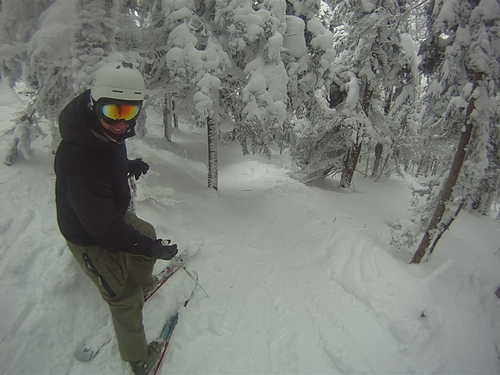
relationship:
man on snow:
[63, 59, 163, 175] [187, 281, 237, 366]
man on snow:
[51, 59, 177, 375] [111, 162, 229, 312]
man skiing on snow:
[51, 59, 177, 375] [303, 199, 418, 309]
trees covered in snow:
[2, 2, 498, 277] [140, 139, 253, 362]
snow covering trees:
[151, 16, 310, 101] [2, 2, 498, 277]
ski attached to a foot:
[74, 243, 198, 375] [130, 338, 165, 373]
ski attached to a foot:
[74, 243, 198, 375] [143, 274, 159, 298]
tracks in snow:
[220, 201, 420, 373] [223, 203, 381, 374]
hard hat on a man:
[88, 66, 145, 139] [51, 59, 177, 375]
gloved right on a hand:
[152, 238, 180, 261] [154, 236, 174, 258]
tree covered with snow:
[193, 10, 250, 207] [242, 57, 284, 101]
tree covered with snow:
[409, 3, 497, 268] [122, 102, 498, 372]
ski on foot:
[74, 243, 198, 375] [137, 336, 154, 373]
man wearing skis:
[51, 59, 177, 375] [75, 237, 198, 371]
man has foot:
[51, 59, 177, 375] [139, 275, 158, 302]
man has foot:
[51, 59, 177, 375] [135, 335, 164, 374]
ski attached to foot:
[74, 243, 198, 375] [139, 275, 158, 302]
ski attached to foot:
[143, 268, 198, 374] [135, 335, 164, 374]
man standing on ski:
[51, 59, 177, 375] [74, 243, 198, 375]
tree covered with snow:
[281, 0, 421, 193] [0, 0, 497, 371]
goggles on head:
[94, 102, 146, 122] [85, 56, 148, 143]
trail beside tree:
[177, 125, 437, 246] [163, 0, 274, 190]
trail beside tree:
[177, 125, 437, 246] [290, 2, 430, 185]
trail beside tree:
[177, 125, 437, 246] [395, 1, 498, 261]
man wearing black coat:
[51, 59, 177, 375] [52, 99, 158, 258]